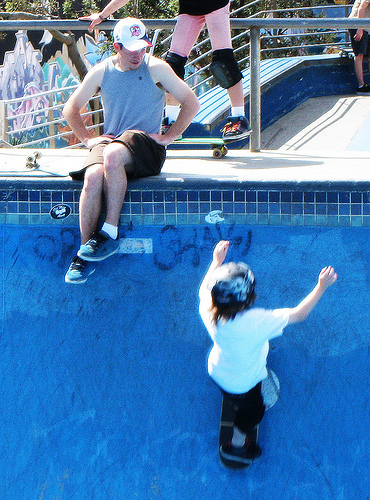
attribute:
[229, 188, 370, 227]
tile — blue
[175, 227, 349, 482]
person — performing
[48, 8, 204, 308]
person — performing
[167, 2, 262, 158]
person — performing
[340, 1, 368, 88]
person — performing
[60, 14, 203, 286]
person — sitting down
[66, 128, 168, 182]
shorts — brown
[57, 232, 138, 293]
sneaker — blue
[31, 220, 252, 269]
graffiti — Undecipherable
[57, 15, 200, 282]
teenager — looking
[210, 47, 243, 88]
knee pad — black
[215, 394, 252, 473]
skateboard — black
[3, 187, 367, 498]
wall — blue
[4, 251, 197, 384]
wall — blue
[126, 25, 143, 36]
logo — red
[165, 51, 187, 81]
knee pad — black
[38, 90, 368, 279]
wall — blue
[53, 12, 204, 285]
adult — sitting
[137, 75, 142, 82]
symbol — tiny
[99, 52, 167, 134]
t shirt — gray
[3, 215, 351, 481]
pool — empty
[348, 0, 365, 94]
person — leaning over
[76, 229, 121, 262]
sneaker — blue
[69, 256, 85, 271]
laces — black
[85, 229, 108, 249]
laces — black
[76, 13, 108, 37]
hand — resting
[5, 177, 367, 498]
pool — empty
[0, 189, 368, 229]
tiles — blue